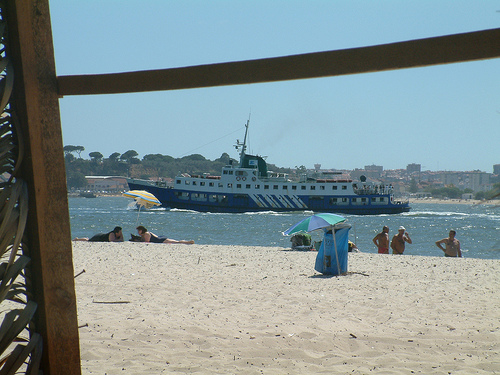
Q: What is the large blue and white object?
A: A large boat.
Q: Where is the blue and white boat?
A: In the water.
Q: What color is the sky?
A: Blue.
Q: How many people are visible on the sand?
A: Five.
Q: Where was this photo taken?
A: At the beach.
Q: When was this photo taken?
A: Outside, during the daytime.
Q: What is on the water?
A: A boat.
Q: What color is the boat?
A: White and blue.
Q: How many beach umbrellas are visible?
A: Two.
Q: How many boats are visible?
A: One.